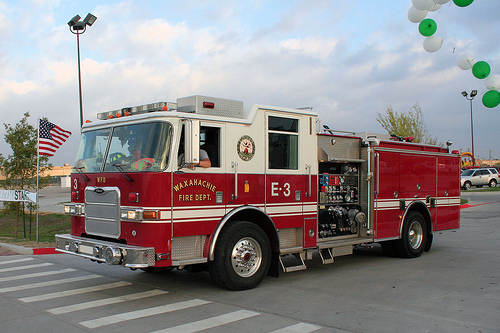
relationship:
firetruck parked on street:
[52, 93, 461, 291] [1, 193, 499, 332]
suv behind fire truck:
[479, 151, 484, 197] [63, 90, 472, 285]